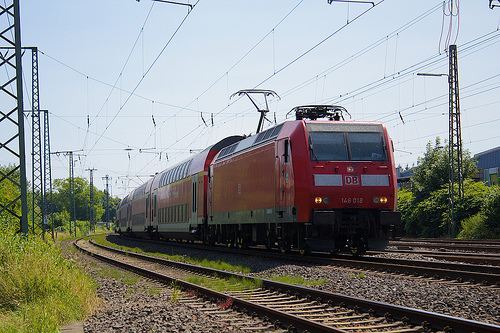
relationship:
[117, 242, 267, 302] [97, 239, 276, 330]
grass patches growing on rails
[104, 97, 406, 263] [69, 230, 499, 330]
train traveling on rails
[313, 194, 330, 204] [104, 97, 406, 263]
headlight of train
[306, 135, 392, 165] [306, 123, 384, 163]
wipers on windshield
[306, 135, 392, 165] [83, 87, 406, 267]
wipers on train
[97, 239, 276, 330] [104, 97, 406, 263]
rails of train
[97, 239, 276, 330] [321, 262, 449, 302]
rails has gravel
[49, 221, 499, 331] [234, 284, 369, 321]
rails has planks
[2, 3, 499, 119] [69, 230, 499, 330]
wires above rails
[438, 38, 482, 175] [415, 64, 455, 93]
pole holding light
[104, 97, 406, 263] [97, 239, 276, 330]
train on rails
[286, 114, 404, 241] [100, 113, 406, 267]
front of train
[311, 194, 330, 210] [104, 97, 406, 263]
headlight on front of train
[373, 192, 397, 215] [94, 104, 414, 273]
headlight on front of train